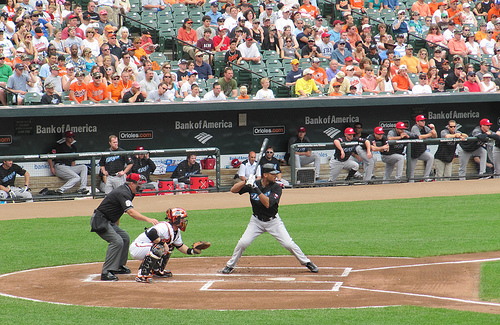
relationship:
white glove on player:
[244, 170, 256, 190] [221, 130, 331, 289]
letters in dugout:
[165, 114, 244, 142] [101, 97, 442, 182]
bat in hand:
[251, 137, 267, 174] [236, 174, 257, 192]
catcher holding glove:
[123, 205, 210, 286] [191, 240, 214, 255]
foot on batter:
[217, 266, 251, 289] [218, 162, 323, 274]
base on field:
[263, 274, 298, 282] [2, 174, 499, 323]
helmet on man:
[258, 164, 283, 179] [258, 155, 289, 181]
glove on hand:
[188, 235, 209, 260] [188, 240, 208, 260]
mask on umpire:
[125, 175, 145, 195] [87, 171, 161, 281]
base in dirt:
[263, 274, 298, 282] [130, 294, 355, 306]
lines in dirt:
[133, 241, 355, 318] [185, 262, 344, 306]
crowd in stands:
[0, 0, 499, 105] [1, 0, 498, 109]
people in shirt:
[2, 4, 499, 109] [120, 80, 133, 95]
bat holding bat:
[251, 137, 267, 174] [232, 120, 339, 200]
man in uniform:
[87, 169, 149, 284] [87, 184, 141, 272]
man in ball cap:
[335, 124, 371, 186] [374, 126, 385, 134]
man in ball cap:
[360, 123, 391, 174] [374, 126, 385, 134]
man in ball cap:
[382, 118, 412, 173] [394, 121, 406, 129]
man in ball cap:
[409, 113, 438, 175] [412, 110, 426, 123]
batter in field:
[218, 155, 325, 277] [4, 199, 484, 306]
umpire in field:
[87, 171, 154, 281] [2, 174, 499, 323]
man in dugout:
[362, 124, 391, 184] [1, 113, 487, 201]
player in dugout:
[475, 104, 486, 196] [1, 113, 487, 201]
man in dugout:
[409, 113, 438, 184] [1, 113, 487, 201]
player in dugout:
[97, 134, 134, 210] [1, 113, 487, 201]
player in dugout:
[45, 127, 84, 197] [1, 113, 487, 201]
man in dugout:
[382, 122, 412, 185] [5, 109, 485, 196]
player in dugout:
[467, 116, 500, 182] [5, 109, 485, 196]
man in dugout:
[330, 124, 372, 186] [5, 109, 485, 196]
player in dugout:
[45, 127, 84, 197] [5, 109, 485, 196]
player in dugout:
[97, 134, 134, 210] [5, 109, 485, 196]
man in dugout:
[409, 113, 438, 184] [0, 103, 500, 200]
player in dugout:
[45, 127, 84, 197] [0, 103, 500, 200]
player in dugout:
[97, 134, 134, 210] [0, 103, 500, 200]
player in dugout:
[170, 151, 201, 183] [0, 103, 500, 200]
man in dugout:
[330, 124, 372, 186] [0, 103, 500, 200]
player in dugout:
[48, 129, 80, 199] [5, 109, 485, 196]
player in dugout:
[167, 152, 213, 188] [5, 109, 485, 196]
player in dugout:
[1, 157, 33, 202] [0, 103, 500, 200]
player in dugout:
[48, 129, 92, 196] [0, 103, 500, 200]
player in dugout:
[97, 132, 125, 185] [0, 103, 500, 200]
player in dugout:
[126, 142, 161, 189] [0, 103, 500, 200]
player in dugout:
[167, 152, 213, 188] [0, 103, 500, 200]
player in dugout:
[286, 122, 323, 187] [0, 103, 500, 200]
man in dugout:
[362, 124, 391, 184] [0, 103, 500, 200]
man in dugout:
[382, 122, 412, 185] [0, 103, 500, 200]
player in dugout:
[433, 117, 470, 173] [0, 103, 500, 200]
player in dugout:
[467, 116, 500, 182] [0, 103, 500, 200]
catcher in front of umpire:
[123, 205, 210, 286] [82, 166, 153, 286]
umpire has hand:
[87, 171, 161, 281] [142, 211, 157, 232]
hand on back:
[142, 211, 157, 232] [134, 220, 168, 238]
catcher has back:
[123, 205, 210, 286] [134, 220, 168, 238]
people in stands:
[44, 0, 495, 173] [4, 3, 484, 94]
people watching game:
[44, 0, 495, 173] [8, 164, 485, 303]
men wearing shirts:
[71, 61, 140, 103] [70, 79, 137, 103]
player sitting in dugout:
[1, 157, 33, 202] [0, 91, 499, 202]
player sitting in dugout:
[45, 127, 84, 197] [0, 91, 499, 202]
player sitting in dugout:
[97, 134, 134, 210] [0, 91, 499, 202]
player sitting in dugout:
[128, 143, 160, 190] [0, 91, 499, 202]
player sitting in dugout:
[170, 151, 201, 183] [0, 91, 499, 202]